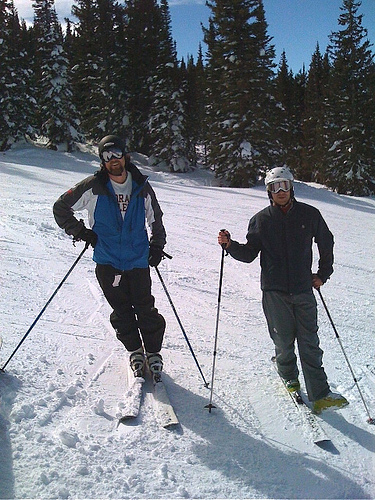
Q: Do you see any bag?
A: No, there are no bags.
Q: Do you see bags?
A: No, there are no bags.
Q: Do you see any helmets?
A: Yes, there is a helmet.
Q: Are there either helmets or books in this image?
A: Yes, there is a helmet.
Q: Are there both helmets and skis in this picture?
A: Yes, there are both a helmet and skis.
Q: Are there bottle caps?
A: No, there are no bottle caps.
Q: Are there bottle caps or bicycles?
A: No, there are no bottle caps or bicycles.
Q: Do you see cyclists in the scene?
A: No, there are no cyclists.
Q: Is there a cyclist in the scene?
A: No, there are no cyclists.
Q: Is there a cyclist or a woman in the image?
A: No, there are no cyclists or women.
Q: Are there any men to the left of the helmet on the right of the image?
A: Yes, there is a man to the left of the helmet.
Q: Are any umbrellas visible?
A: No, there are no umbrellas.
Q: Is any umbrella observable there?
A: No, there are no umbrellas.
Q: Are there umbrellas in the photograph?
A: No, there are no umbrellas.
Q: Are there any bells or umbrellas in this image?
A: No, there are no umbrellas or bells.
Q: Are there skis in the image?
A: Yes, there are skis.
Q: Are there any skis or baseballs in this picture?
A: Yes, there are skis.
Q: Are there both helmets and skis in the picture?
A: Yes, there are both skis and a helmet.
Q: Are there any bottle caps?
A: No, there are no bottle caps.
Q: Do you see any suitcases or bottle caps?
A: No, there are no bottle caps or suitcases.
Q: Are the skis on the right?
A: Yes, the skis are on the right of the image.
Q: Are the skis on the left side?
A: No, the skis are on the right of the image.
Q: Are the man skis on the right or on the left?
A: The skis are on the right of the image.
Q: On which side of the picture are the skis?
A: The skis are on the right of the image.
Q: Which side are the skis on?
A: The skis are on the right of the image.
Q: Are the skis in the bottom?
A: Yes, the skis are in the bottom of the image.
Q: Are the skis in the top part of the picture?
A: No, the skis are in the bottom of the image.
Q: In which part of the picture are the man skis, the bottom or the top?
A: The skis are in the bottom of the image.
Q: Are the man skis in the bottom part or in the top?
A: The skis are in the bottom of the image.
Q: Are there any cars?
A: No, there are no cars.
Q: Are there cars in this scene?
A: No, there are no cars.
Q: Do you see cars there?
A: No, there are no cars.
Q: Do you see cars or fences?
A: No, there are no cars or fences.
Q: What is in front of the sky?
A: The trees are in front of the sky.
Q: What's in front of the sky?
A: The trees are in front of the sky.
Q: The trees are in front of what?
A: The trees are in front of the sky.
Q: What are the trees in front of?
A: The trees are in front of the sky.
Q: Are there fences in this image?
A: No, there are no fences.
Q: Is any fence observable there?
A: No, there are no fences.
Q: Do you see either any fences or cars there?
A: No, there are no fences or cars.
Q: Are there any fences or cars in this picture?
A: No, there are no fences or cars.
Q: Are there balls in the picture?
A: No, there are no balls.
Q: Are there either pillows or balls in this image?
A: No, there are no balls or pillows.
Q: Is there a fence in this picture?
A: No, there are no fences.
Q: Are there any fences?
A: No, there are no fences.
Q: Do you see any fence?
A: No, there are no fences.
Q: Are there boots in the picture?
A: Yes, there are boots.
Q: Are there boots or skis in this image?
A: Yes, there are boots.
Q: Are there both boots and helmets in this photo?
A: Yes, there are both boots and a helmet.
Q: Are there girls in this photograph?
A: No, there are no girls.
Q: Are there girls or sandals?
A: No, there are no girls or sandals.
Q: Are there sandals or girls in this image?
A: No, there are no girls or sandals.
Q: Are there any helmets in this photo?
A: Yes, there is a helmet.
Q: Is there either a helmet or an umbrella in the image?
A: Yes, there is a helmet.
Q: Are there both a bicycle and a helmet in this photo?
A: No, there is a helmet but no bicycles.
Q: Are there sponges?
A: No, there are no sponges.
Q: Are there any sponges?
A: No, there are no sponges.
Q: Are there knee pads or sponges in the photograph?
A: No, there are no sponges or knee pads.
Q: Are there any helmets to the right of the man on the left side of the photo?
A: Yes, there is a helmet to the right of the man.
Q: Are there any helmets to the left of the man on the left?
A: No, the helmet is to the right of the man.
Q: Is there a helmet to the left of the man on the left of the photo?
A: No, the helmet is to the right of the man.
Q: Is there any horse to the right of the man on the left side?
A: No, there is a helmet to the right of the man.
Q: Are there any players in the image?
A: No, there are no players.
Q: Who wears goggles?
A: The man wears goggles.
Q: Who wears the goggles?
A: The man wears goggles.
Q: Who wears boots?
A: The man wears boots.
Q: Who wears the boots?
A: The man wears boots.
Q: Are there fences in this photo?
A: No, there are no fences.